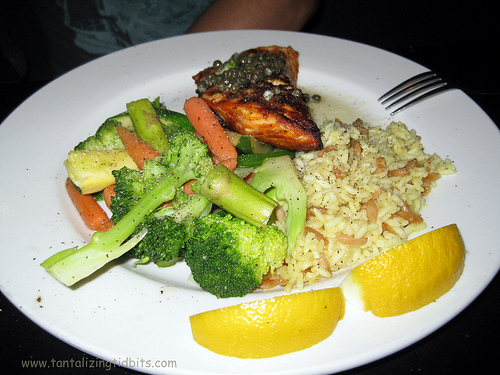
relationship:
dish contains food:
[0, 28, 500, 374] [42, 47, 463, 359]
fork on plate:
[377, 71, 456, 116] [25, 94, 437, 355]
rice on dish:
[256, 118, 457, 293] [0, 28, 500, 374]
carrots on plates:
[182, 95, 244, 172] [10, 21, 496, 360]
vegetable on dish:
[39, 132, 306, 298] [0, 28, 500, 374]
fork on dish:
[367, 52, 463, 131] [0, 28, 500, 374]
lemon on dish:
[186, 287, 352, 357] [5, 27, 499, 373]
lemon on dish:
[347, 220, 472, 319] [5, 27, 499, 373]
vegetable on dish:
[126, 126, 306, 261] [35, 21, 483, 116]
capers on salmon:
[204, 47, 284, 104] [191, 43, 325, 152]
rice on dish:
[302, 124, 437, 264] [0, 28, 500, 374]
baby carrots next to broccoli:
[182, 92, 242, 166] [152, 206, 270, 291]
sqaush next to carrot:
[59, 150, 142, 197] [67, 180, 112, 231]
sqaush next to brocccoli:
[59, 150, 142, 197] [77, 117, 129, 159]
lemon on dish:
[339, 224, 465, 319] [0, 28, 500, 374]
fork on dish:
[377, 71, 456, 116] [0, 28, 500, 374]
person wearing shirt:
[50, 9, 354, 77] [48, 0, 220, 56]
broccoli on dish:
[67, 77, 305, 279] [0, 28, 500, 374]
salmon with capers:
[191, 43, 325, 152] [197, 47, 287, 96]